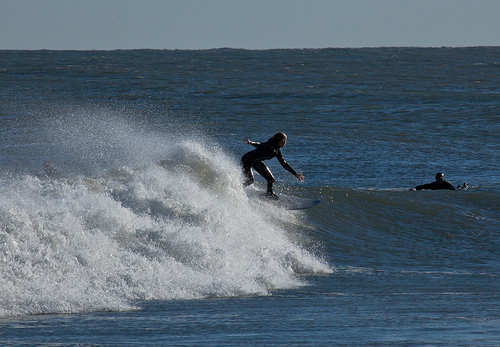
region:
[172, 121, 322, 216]
a person surfing the ocean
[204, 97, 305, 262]
a woman surfing in the water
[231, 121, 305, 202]
a woman wearing a wet suit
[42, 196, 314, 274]
a white wave in the ocean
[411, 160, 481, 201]
a man laying down on a surf board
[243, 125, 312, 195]
a woman with her arms stretched out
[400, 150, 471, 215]
a man in the water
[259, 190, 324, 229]
a blue and white surf board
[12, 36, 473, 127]
the ocean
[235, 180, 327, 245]
a surf board in the water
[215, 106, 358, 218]
This is a surfer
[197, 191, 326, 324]
The waves are white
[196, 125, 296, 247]
This is a wetsuit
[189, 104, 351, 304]
the wetsuit is black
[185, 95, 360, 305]
this is a woman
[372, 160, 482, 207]
this is a man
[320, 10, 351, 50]
there are no clouds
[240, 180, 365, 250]
this is a surfboard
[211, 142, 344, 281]
the board is white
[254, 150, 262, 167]
the board is blue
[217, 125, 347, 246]
a surfer riding a wave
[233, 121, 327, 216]
a person on a surfboard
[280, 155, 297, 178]
the right arm of a person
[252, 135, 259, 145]
the left arm of a person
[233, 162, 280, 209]
a person standing on a surfboard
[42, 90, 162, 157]
white water spray from a wave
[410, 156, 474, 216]
a person in the water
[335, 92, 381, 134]
the choppy surface of the water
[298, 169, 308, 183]
the right hand of a person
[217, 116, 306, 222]
a person wearing a wet suit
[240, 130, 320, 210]
Athlete surfing on the ocean.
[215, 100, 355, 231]
A woman sketing in water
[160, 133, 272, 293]
White water form from the skate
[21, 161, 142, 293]
White water form from the skate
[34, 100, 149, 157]
White water form from the skate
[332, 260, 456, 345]
Blue water in the sea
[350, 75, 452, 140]
Blue water in the sea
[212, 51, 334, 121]
Blue water in the sea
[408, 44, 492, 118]
Blue water in the sea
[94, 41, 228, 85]
Blue water in the sea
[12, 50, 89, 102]
Blue water in the sea